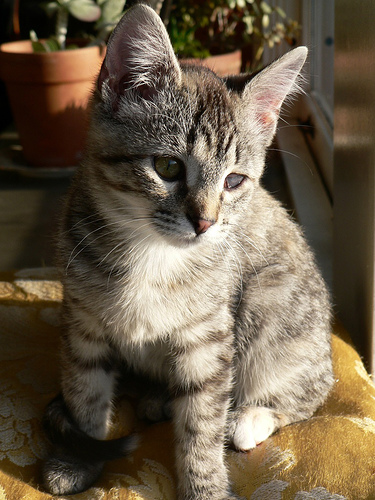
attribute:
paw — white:
[226, 399, 299, 463]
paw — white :
[227, 402, 278, 452]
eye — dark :
[142, 145, 192, 192]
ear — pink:
[93, 4, 184, 105]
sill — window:
[272, 113, 335, 301]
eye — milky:
[224, 166, 252, 190]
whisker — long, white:
[225, 237, 246, 309]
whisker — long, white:
[240, 242, 262, 292]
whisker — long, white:
[67, 201, 157, 226]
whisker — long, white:
[93, 228, 142, 267]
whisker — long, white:
[127, 231, 151, 253]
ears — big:
[95, 4, 310, 147]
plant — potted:
[25, 0, 103, 49]